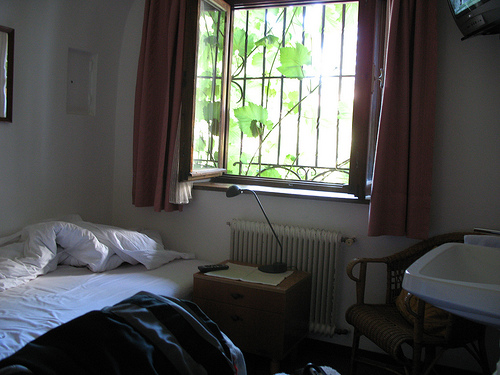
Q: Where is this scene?
A: A bedroom.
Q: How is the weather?
A: Sunny.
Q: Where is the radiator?
A: Under the window.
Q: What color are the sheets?
A: White.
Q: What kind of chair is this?
A: Wicker.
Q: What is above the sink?
A: A television.